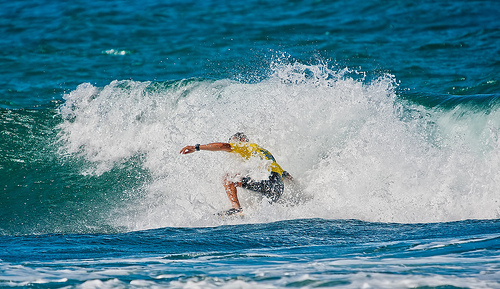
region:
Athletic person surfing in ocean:
[179, 129, 316, 216]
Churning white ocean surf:
[82, 100, 134, 131]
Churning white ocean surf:
[213, 99, 283, 124]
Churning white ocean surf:
[332, 88, 386, 136]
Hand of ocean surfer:
[175, 143, 205, 157]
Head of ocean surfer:
[228, 131, 253, 142]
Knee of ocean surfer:
[222, 174, 237, 188]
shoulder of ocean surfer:
[236, 142, 251, 157]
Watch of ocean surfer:
[191, 140, 201, 154]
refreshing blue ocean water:
[119, 23, 184, 48]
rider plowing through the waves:
[20, 11, 470, 276]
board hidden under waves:
[187, 196, 319, 231]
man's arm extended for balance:
[176, 135, 223, 156]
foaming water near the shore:
[106, 257, 278, 283]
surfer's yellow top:
[226, 137, 277, 167]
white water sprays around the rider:
[175, 100, 330, 215]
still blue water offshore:
[316, 2, 461, 49]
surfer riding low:
[125, 42, 380, 248]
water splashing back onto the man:
[235, 151, 272, 181]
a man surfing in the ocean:
[25, 7, 465, 265]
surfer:
[174, 134, 311, 237]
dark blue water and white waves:
[392, 53, 461, 119]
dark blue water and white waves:
[399, 126, 457, 172]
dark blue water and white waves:
[387, 184, 445, 248]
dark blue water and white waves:
[323, 66, 387, 105]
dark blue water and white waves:
[94, 194, 204, 265]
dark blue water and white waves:
[55, 48, 131, 133]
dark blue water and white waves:
[158, 28, 220, 88]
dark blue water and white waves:
[44, 164, 104, 231]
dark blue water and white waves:
[251, 37, 367, 101]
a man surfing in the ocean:
[181, 135, 297, 217]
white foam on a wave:
[49, 45, 499, 231]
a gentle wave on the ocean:
[1, 256, 497, 287]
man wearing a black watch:
[195, 143, 201, 153]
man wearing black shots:
[243, 170, 282, 200]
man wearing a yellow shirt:
[230, 138, 281, 174]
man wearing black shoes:
[223, 208, 243, 216]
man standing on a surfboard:
[178, 133, 290, 218]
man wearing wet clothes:
[221, 130, 289, 219]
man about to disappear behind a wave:
[180, 130, 292, 215]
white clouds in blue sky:
[30, 5, 124, 46]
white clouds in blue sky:
[366, 17, 421, 47]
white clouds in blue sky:
[333, 30, 397, 69]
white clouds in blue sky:
[437, 3, 481, 42]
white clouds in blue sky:
[260, 37, 345, 81]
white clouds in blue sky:
[155, 26, 233, 72]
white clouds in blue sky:
[74, 23, 132, 58]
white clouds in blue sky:
[119, 35, 186, 79]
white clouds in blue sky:
[46, 17, 142, 79]